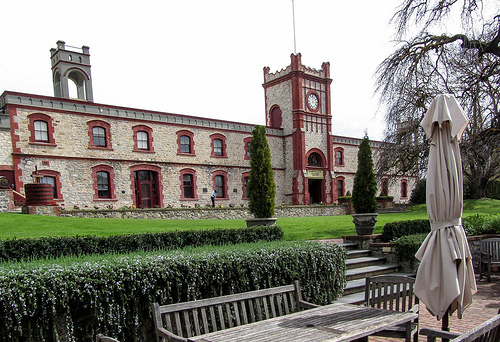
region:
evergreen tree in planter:
[245, 124, 277, 226]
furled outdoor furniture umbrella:
[416, 81, 476, 331]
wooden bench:
[147, 279, 325, 338]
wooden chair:
[365, 273, 415, 312]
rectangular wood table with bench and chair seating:
[150, 274, 498, 339]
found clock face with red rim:
[303, 91, 321, 110]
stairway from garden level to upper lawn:
[312, 235, 409, 295]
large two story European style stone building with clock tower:
[3, 2, 430, 205]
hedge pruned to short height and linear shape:
[2, 235, 343, 340]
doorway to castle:
[131, 167, 165, 208]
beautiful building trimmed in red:
[0, 43, 418, 215]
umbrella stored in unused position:
[413, 91, 480, 340]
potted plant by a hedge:
[243, 125, 278, 228]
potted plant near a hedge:
[351, 131, 377, 234]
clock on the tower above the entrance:
[304, 90, 321, 111]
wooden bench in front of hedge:
[151, 279, 317, 340]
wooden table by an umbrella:
[189, 302, 416, 340]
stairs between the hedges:
[325, 243, 403, 293]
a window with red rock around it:
[85, 118, 111, 152]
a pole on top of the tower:
[286, 0, 299, 54]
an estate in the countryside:
[11, 0, 479, 327]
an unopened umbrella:
[411, 80, 478, 305]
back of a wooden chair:
[356, 270, 416, 310]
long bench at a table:
[142, 276, 312, 323]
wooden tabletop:
[280, 301, 412, 336]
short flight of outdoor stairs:
[336, 241, 387, 283]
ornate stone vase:
[346, 207, 381, 238]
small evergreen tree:
[345, 126, 377, 238]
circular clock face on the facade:
[300, 85, 323, 115]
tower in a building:
[257, 57, 337, 132]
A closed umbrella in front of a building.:
[409, 42, 483, 338]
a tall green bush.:
[231, 112, 288, 234]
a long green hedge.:
[0, 203, 497, 262]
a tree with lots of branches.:
[369, 2, 498, 215]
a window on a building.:
[128, 164, 165, 212]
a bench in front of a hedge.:
[156, 277, 329, 338]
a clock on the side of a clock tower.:
[302, 89, 324, 114]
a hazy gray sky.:
[0, 1, 396, 144]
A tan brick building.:
[0, 35, 441, 215]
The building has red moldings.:
[0, 35, 441, 210]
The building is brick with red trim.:
[2, 46, 442, 210]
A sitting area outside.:
[138, 265, 499, 340]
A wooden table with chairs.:
[117, 262, 497, 340]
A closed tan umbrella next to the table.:
[406, 81, 483, 339]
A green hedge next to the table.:
[3, 205, 496, 339]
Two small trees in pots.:
[234, 122, 385, 240]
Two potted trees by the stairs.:
[241, 129, 401, 294]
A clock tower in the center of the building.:
[265, 52, 345, 209]